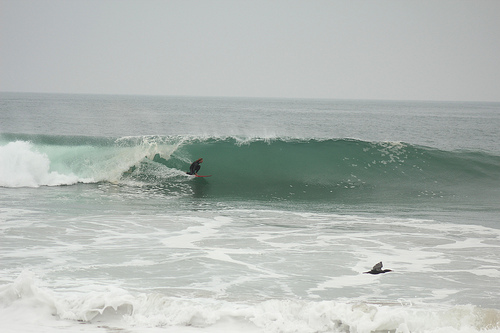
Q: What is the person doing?
A: Surfing.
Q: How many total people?
A: 1.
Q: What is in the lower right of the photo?
A: Bird.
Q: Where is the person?
A: On the surfboard.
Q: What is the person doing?
A: Surfing.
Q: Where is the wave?
A: Behind the person.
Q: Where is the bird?
A: In the air.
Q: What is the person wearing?
A: A wetsuit.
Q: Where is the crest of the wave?
A: Above the person.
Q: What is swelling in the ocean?
A: The waves.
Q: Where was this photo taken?
A: In the Ocean.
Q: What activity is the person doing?
A: Surfing.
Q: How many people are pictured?
A: One.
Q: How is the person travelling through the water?
A: By surfing.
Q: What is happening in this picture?
A: Two people are surfing.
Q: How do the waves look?
A: Rough.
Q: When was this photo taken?
A: During the day.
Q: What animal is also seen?
A: A bird.